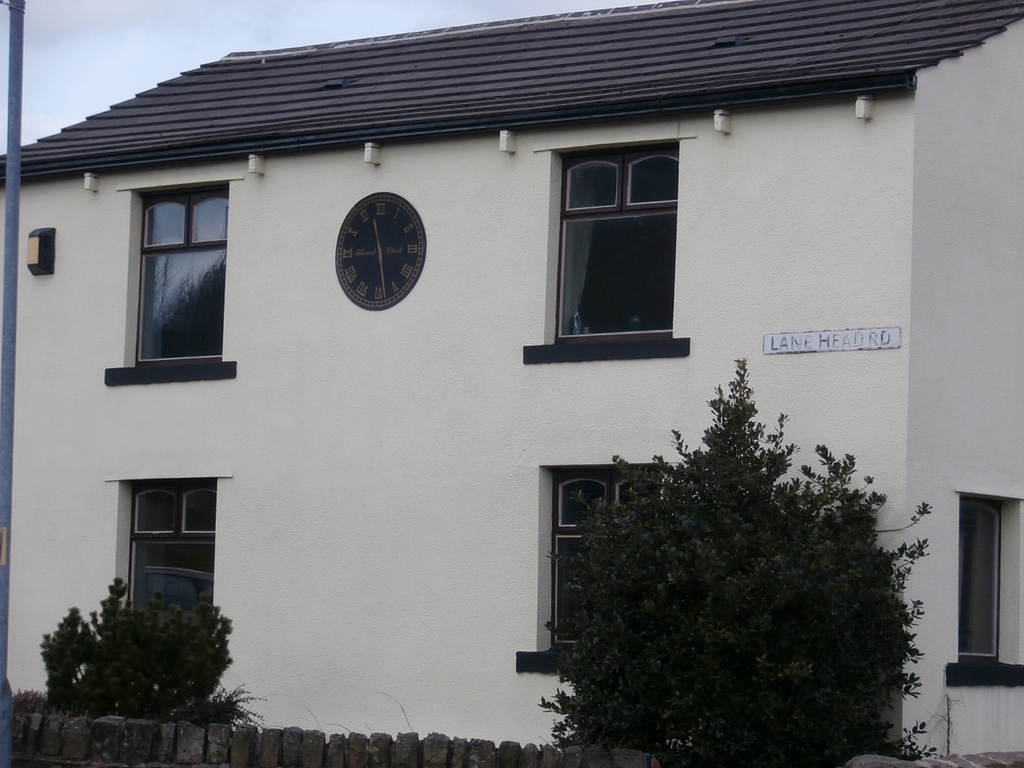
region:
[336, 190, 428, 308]
a clock on the side of a house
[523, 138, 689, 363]
a rectangular window and sill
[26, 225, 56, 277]
a decoration on the outside of a house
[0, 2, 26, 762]
a metal pole outside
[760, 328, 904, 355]
a road sign on the side of a house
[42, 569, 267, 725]
a bush in front of a house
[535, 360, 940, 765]
a tree in front of a house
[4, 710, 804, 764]
the top of a fence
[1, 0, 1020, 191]
a shingled brown roof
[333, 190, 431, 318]
Clock face reads 11:29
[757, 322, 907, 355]
Sign for Lane Head Rd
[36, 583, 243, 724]
Small bush in front of bottom window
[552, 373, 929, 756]
Large bush in front of bottom story window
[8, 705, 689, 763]
Stone fence beside house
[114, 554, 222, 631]
Reflection of car in window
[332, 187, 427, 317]
Clock with Roman numerals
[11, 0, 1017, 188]
Slate rooftop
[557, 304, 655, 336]
Tchotchkes in window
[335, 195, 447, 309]
Clock is fixed to the building wall.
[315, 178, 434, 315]
Clock is black and brown color.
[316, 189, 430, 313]
Numbers are roman letters.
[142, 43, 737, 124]
Roof is brown color.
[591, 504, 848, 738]
Leaves are green color.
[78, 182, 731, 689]
Windows are attached to the wall.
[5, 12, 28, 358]
Pole is grey color.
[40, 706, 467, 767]
fence is grey color.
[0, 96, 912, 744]
a clock on the white wall of a building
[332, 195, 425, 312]
a black and golden clock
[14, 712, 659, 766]
a small wooden fence made of vertical logs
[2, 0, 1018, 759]
a metal pole in front of a white building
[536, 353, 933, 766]
a small lush green tree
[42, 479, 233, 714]
a window behind a small green bush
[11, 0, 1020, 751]
a black roof on top of a white building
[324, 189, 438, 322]
a big black wall clock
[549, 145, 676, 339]
Window of a house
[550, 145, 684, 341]
Window of a tan house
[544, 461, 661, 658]
Window of a house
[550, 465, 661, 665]
Window of a tan house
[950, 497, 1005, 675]
Window of a house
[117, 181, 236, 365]
Window of a house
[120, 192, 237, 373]
Window of a tan house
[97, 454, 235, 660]
Window of a house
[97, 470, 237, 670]
Window of a tan house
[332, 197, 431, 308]
the clock is black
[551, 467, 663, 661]
window on the wall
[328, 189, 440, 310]
a clock on the house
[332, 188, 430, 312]
round black clock face with gold numerals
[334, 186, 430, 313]
round black clock face with gold hands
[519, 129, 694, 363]
square window beneath small plates of glass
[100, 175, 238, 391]
square window beneath small plates of glass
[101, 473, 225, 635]
square window beneath small plates of glass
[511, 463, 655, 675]
square window beneath small plates of glass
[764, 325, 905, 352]
white sign with black letters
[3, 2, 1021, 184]
white building with dark gray roof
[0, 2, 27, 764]
tall silver metal pole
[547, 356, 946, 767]
tall green bush beside white building